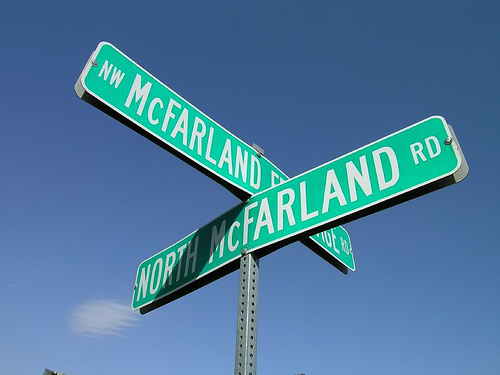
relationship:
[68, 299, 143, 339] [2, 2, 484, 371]
cloud hanging in sky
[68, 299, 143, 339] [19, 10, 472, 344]
cloud hanging in sky